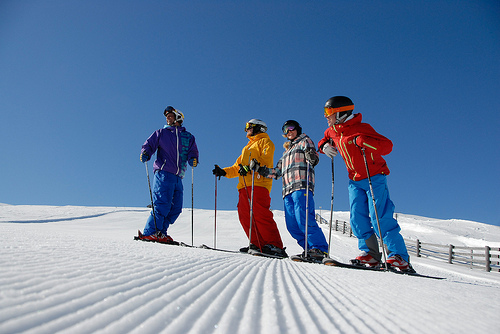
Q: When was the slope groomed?
A: Recently.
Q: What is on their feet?
A: Snow Skis.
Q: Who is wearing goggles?
A: Everyone.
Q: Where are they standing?
A: On a mountain.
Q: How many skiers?
A: 4.